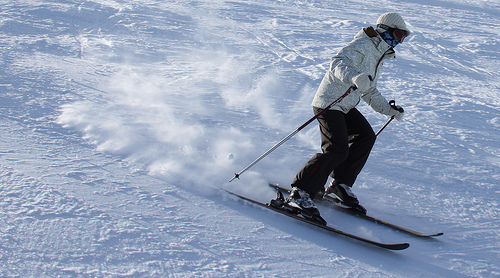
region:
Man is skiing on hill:
[229, 10, 450, 257]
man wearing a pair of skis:
[222, 154, 448, 256]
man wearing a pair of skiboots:
[270, 175, 362, 222]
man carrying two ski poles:
[229, 83, 404, 205]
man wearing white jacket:
[311, 16, 408, 122]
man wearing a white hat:
[371, 3, 411, 34]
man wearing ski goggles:
[380, 20, 410, 44]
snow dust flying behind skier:
[66, 37, 316, 208]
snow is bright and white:
[6, 3, 496, 271]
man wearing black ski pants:
[288, 103, 378, 194]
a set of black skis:
[225, 181, 445, 254]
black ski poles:
[225, 73, 373, 184]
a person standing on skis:
[224, 10, 442, 251]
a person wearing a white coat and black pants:
[287, 12, 411, 214]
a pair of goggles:
[374, 23, 409, 40]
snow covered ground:
[3, 3, 497, 276]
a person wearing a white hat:
[283, 11, 411, 216]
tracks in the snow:
[2, 4, 499, 276]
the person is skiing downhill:
[226, 17, 443, 252]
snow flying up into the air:
[56, 53, 332, 194]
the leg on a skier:
[341, 110, 381, 191]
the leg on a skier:
[291, 110, 351, 193]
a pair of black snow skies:
[225, 182, 447, 262]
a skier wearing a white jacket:
[308, 7, 415, 112]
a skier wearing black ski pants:
[291, 6, 412, 218]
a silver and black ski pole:
[221, 82, 355, 187]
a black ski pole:
[373, 107, 400, 139]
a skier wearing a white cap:
[367, 9, 417, 54]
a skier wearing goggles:
[379, 25, 410, 47]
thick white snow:
[1, 0, 215, 276]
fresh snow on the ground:
[22, 140, 111, 197]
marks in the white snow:
[42, 176, 142, 242]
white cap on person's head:
[377, 5, 420, 27]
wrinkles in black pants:
[279, 162, 324, 184]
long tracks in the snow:
[247, 30, 298, 67]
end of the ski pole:
[228, 166, 260, 191]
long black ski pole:
[226, 112, 344, 160]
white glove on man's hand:
[343, 69, 381, 104]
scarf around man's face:
[365, 16, 415, 59]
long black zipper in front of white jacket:
[369, 41, 391, 93]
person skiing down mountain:
[319, 11, 426, 256]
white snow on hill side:
[35, 32, 77, 95]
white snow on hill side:
[51, 112, 101, 153]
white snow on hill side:
[80, 198, 141, 230]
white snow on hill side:
[133, 47, 210, 109]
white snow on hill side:
[430, 117, 489, 167]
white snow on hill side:
[421, 36, 478, 113]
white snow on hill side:
[238, 10, 278, 59]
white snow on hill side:
[117, 163, 157, 208]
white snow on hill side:
[204, 217, 257, 259]